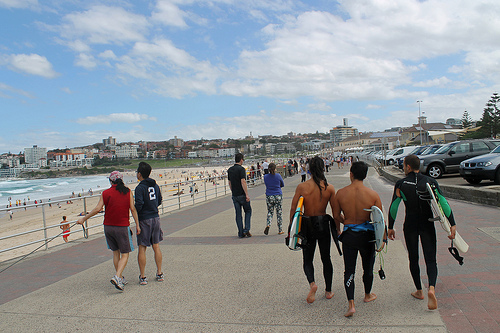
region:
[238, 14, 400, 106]
A white cloud is in the sky.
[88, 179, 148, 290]
She is wearing a red shirt.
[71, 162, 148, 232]
She is wearing a hat.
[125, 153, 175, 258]
He is wearing grey shorts.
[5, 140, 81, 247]
The shore has lots of people on it.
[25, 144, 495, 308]
Many people are walking along the beach.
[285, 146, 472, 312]
They have surf boards.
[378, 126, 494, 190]
The cars are parked.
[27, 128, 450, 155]
The buildings are along the shore.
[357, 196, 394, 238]
The board is white.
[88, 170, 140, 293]
Lady in red walking pet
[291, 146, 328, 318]
Shirtless surfer holding board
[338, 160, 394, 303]
Shirtless surfer holding board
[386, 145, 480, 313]
Surfer in black wetsuit holding board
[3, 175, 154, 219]
Midly rough ocean on left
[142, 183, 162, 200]
White number 2 on black hoodie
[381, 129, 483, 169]
Parking lot off to the right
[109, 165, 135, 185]
Pink and white cap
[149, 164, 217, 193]
beachgoers and sun bathers on beach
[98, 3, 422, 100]
Partly cloudy sky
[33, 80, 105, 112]
this is the sky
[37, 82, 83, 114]
the sky is blue in color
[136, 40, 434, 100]
the sky has some clouds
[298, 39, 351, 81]
the clouds are white in color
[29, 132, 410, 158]
these are several buildings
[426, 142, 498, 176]
these are some cars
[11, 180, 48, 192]
the water is blue in color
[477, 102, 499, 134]
this is a tree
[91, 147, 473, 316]
these are several people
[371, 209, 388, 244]
this is a surfboard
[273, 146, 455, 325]
three surfers carrying their boards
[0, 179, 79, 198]
waves rolling in to shore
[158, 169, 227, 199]
a crowd hanging out on the beach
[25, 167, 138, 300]
a woman hanging onto a rope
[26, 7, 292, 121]
a b;ue sky with fluffy white clouds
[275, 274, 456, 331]
three people walking with bare feet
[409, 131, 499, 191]
cars parked in the parking lot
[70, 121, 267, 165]
many buildings in the background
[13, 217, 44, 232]
the beach covered with sand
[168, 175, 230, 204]
a fence dividing the street from the beach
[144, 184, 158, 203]
The number 2 on the back of the man's sweater.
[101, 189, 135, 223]
The red shirt the lady is wearing.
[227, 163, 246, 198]
The black t-shirt the man is wearing.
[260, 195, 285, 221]
The black and white pants the lady is wearing.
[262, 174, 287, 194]
The blue sweater the lady is wearing.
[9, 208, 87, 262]
The leash the lady in red is holding.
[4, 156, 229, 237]
The people on the sand area of the beach.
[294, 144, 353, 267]
The guy carrying a surfboard with long hair.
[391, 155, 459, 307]
The guy carrying a surfboard in the black wet suit.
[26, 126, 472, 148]
The buildings in the distance.